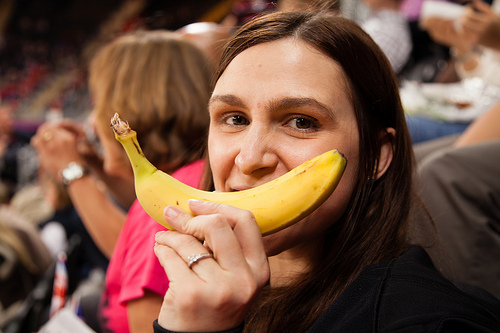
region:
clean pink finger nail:
[163, 202, 180, 219]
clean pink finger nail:
[155, 228, 168, 246]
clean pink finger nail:
[188, 196, 204, 213]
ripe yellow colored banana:
[103, 109, 347, 241]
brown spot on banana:
[173, 199, 178, 206]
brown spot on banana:
[152, 202, 158, 207]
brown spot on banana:
[311, 180, 324, 192]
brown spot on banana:
[298, 165, 310, 175]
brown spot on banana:
[128, 138, 145, 156]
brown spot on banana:
[116, 135, 126, 140]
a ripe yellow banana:
[97, 113, 362, 238]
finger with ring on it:
[148, 223, 223, 280]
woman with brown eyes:
[156, 7, 489, 332]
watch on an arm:
[29, 118, 136, 261]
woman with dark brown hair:
[150, 5, 497, 331]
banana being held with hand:
[99, 106, 354, 331]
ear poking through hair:
[362, 111, 421, 198]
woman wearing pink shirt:
[83, 24, 223, 329]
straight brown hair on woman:
[115, 8, 452, 332]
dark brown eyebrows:
[202, 88, 353, 130]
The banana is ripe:
[73, 105, 375, 247]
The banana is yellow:
[88, 90, 357, 250]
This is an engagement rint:
[176, 241, 219, 273]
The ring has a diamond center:
[178, 249, 206, 270]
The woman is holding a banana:
[106, 8, 427, 315]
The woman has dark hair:
[136, 5, 464, 317]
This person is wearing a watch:
[28, 155, 98, 205]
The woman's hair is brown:
[199, 5, 449, 317]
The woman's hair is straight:
[193, 0, 434, 313]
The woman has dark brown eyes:
[198, 82, 368, 148]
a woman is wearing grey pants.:
[446, 172, 486, 262]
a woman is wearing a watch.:
[48, 147, 95, 196]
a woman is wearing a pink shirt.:
[121, 226, 149, 281]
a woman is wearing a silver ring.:
[171, 240, 221, 276]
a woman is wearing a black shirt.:
[366, 279, 429, 331]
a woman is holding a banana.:
[103, 101, 353, 258]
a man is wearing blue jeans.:
[405, 116, 467, 146]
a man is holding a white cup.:
[410, 0, 493, 54]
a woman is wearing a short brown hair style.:
[79, 31, 217, 166]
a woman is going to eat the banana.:
[38, 3, 490, 331]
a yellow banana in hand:
[83, 107, 391, 254]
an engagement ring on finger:
[179, 245, 224, 286]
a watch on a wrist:
[57, 147, 92, 194]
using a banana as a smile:
[78, 100, 385, 247]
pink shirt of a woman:
[58, 157, 229, 331]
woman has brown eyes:
[214, 102, 363, 156]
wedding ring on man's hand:
[34, 123, 64, 148]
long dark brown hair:
[202, 11, 459, 331]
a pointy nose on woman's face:
[228, 130, 285, 184]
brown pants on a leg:
[416, 127, 499, 314]